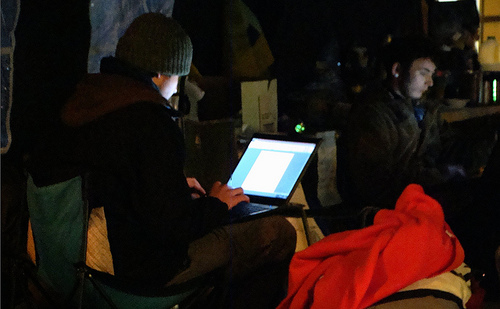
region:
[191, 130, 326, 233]
A laptop computer on a lap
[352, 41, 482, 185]
A man looking at a computer screen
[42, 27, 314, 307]
A man working on a laptop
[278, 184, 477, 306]
A red blanket tossed aside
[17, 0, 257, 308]
A man sitting in a lawn chair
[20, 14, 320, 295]
A man on a computer in lawn chair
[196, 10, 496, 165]
A table top cluttered with boxes and dishes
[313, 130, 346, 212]
A piece of paper hanging from a table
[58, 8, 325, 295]
A man surfing the internet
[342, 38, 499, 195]
A man working on his computer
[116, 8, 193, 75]
man wearing a green wool hat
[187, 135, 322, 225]
man typing on a laptop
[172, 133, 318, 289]
an illuminated laptop on man's lap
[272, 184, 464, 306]
a red coat on an armrest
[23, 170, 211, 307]
a green folding chair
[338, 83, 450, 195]
man wearing a brown coat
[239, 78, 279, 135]
a menu propped upright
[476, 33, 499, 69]
a jug of milk with a blue top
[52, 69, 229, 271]
man wearing a coat with a hood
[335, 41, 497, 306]
a man sitting in a chair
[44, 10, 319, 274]
man is sitting down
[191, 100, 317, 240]
the man is using his laptop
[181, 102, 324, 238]
the lap top is open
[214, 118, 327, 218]
the lap top screen is bright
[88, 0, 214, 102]
man is wearing a hat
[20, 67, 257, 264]
man is wearing a coat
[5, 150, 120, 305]
the chair is green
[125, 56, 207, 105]
the screen light is on the man`s face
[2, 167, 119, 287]
a pillow on the back of the chair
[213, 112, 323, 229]
the lap top is black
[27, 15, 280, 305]
this is a person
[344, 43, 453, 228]
this is a person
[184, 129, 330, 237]
this is a laptop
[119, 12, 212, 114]
the head of a man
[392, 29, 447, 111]
the head of a man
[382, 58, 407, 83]
the ear of a man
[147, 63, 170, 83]
the ear of a man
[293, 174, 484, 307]
this is a red cloth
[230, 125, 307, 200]
the screen of a laptop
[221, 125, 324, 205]
the laptop os on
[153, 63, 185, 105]
a face with a light shining on it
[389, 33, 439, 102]
a head of a person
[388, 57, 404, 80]
the ear of a person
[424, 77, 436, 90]
the nose of a person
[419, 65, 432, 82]
the eye of a person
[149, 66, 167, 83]
the ear of a person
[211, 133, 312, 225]
a laptop sitting on a lap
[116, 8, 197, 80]
a stocking cap on a head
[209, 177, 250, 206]
a hand of a person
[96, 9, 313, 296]
a person with a laptop on his lap